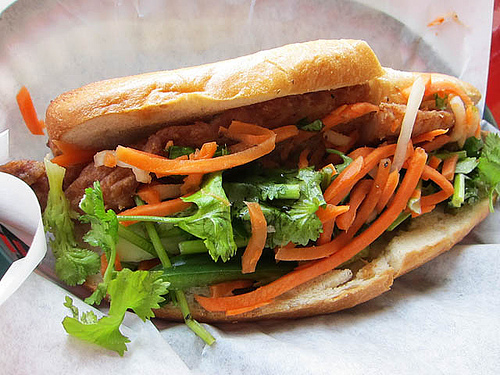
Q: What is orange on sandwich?
A: The carrots.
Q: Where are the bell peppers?
A: On sandwich.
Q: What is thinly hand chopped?
A: The carrots.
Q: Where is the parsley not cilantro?
A: On sandwich.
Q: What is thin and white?
A: Shredded onion.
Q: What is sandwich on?
A: White wax deli paper.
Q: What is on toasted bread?
A: Sandwich.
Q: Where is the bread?
A: On the table.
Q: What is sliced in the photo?
A: Carrots.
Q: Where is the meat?
A: Inside light bread.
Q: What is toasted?
A: The bread.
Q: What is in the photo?
A: Vegetables.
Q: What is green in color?
A: Lettuce.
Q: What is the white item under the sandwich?
A: Wax paper.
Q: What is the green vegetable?
A: Lettuce.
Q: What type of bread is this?
A: White.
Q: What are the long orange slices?
A: Carrots.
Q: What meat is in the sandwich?
A: Chicken.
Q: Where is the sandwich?
A: In a basket.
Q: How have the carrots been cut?
A: Into thin slices.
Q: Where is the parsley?
A: Scattered on top of sandwich.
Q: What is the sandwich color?
A: Tan.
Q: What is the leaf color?
A: Green.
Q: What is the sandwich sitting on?
A: Paper.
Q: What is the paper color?
A: White.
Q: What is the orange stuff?
A: Carrot.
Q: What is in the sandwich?
A: Lettuce, carrots and onion.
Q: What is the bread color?
A: White.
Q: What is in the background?
A: Paper.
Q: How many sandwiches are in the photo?
A: One.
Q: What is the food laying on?
A: Paper.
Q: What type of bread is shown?
A: A bun.